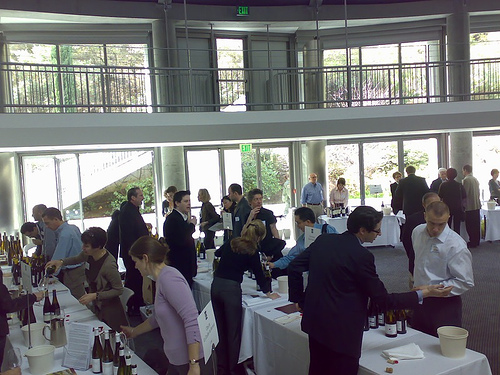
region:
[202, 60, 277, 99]
the railing is gray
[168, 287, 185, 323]
the jacket is lavender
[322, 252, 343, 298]
the jacket is black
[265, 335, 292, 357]
the tablecloth is white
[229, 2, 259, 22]
the word is neon green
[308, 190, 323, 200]
the shirt is blue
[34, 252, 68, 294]
she is pouring the wine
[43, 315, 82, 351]
the pitcher is silver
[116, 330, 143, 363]
the glass is clear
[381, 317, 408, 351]
the label is white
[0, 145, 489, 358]
People at a wine tasting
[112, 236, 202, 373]
A woman in a lavender sweater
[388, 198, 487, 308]
A man in a white dress shirt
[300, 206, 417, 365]
A man wearing glasses in a dark suit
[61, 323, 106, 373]
Wine information pamphlets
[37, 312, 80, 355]
A metal pitcher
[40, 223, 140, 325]
A woman wearing a brown sweater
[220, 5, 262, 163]
Two green exit signs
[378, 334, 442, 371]
A white cloth napkin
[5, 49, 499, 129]
Metal railing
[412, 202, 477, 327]
Man wearing white button down shirt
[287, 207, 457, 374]
Man showing man card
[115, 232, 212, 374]
Woman wearing lilac cardigan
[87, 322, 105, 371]
Wine bottle on table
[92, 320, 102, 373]
Wine bottle next to wine bottle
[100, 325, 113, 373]
Wine bottle next to wine bottle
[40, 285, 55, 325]
Wine bottle next to wine bottle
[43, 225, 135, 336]
Woman pouring wine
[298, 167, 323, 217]
Man in blue button down shirt standing by door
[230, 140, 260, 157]
EXIT sign by door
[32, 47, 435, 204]
It is sunny outside.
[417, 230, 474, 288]
The man is wearing a white shirt.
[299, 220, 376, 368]
The man is wearing a black suit.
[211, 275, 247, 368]
The woman is wearing grey pants.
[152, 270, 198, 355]
The woman is wearing a purple shirt.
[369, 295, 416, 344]
The bottles are wine bottles.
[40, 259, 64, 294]
The woman is pouring some wine.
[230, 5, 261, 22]
The exit sign is green.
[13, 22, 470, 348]
The event is a wine convention.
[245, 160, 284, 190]
The bush outside is green.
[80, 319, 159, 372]
bottles of wine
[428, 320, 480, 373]
white buckets on a table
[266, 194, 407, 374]
man in a dark suite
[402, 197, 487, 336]
man in a white dress shirt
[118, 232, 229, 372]
woman wearing a pink shirt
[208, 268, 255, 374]
grey women's pants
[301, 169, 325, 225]
elderly man in a blue shirt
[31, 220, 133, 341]
woman pouring a glass of wine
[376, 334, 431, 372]
folded white cloth on table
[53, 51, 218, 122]
grey safety railing